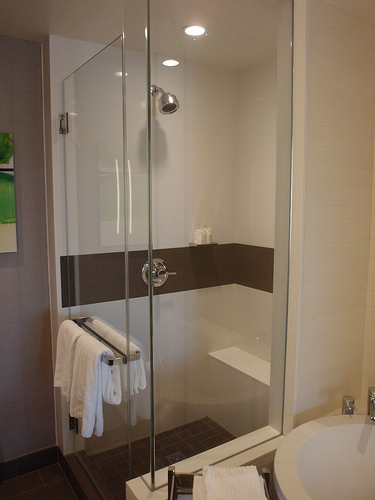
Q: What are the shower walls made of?
A: Clear glass.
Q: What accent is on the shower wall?
A: A brown stripe.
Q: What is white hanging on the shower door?
A: Towels.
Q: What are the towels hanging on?
A: A glass door.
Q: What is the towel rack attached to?
A: A glass shower door.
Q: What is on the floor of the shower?
A: Brown tile.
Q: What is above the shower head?
A: Lights.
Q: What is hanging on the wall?
A: A picture.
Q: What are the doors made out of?
A: Made out of glass.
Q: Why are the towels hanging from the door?
A: Because it is a shower.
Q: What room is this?
A: The bathroom.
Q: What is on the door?
A: Towels.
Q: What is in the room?
A: A bathroom.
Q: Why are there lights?
A: So people can see.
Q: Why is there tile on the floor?
A: For decoration.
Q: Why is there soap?
A: It is a bathroom.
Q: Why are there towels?
A: To dry hands off.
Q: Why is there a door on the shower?
A: To keep water in.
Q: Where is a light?
A: On the ceiling.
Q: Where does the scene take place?
A: In a bathroom.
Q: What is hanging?
A: Towels.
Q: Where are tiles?
A: On the floor.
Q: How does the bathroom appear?
A: Neat and tidy.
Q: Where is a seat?
A: In the shower.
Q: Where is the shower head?
A: On the shower wall.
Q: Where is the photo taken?
A: Bathroom.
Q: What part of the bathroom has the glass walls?
A: Shower.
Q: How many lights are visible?
A: Two.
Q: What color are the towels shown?
A: White.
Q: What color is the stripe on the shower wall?
A: Brown.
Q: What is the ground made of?
A: Tile.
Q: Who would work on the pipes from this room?
A: Plumber.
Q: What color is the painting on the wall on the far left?
A: Green.